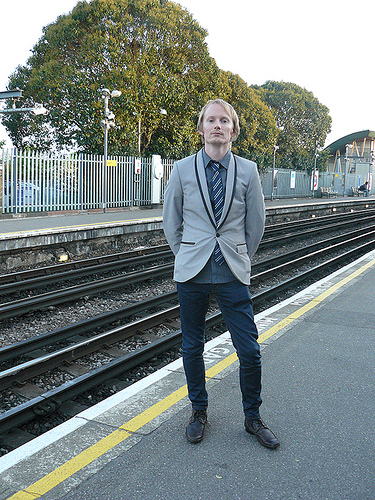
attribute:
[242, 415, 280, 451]
shoe — black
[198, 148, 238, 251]
tie — blue, gray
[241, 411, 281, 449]
shoe — black